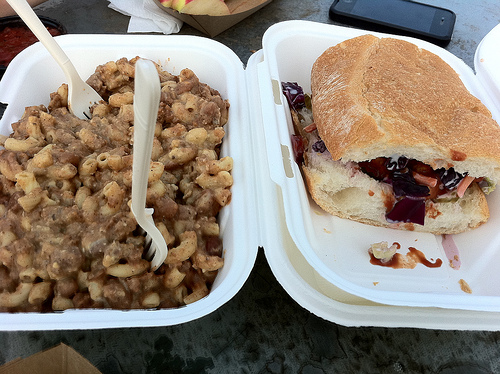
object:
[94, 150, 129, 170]
piece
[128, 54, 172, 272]
fork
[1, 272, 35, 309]
macaroni piece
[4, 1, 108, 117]
fork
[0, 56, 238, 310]
food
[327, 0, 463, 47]
smartphone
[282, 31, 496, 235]
sandwich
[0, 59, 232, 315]
macaroni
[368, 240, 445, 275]
sauce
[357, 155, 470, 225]
sauce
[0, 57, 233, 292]
casserole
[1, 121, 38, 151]
noodle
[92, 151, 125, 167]
noodle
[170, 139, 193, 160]
noodle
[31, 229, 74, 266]
meat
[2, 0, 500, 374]
tabletop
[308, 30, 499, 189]
top bread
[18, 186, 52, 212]
maccaroni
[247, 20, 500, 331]
box